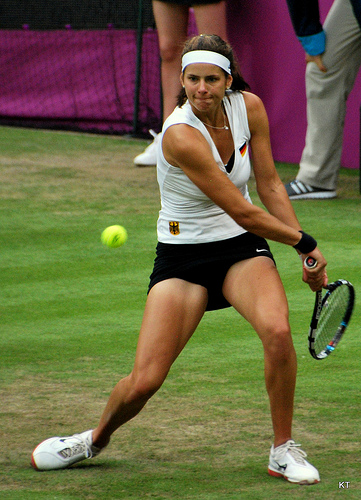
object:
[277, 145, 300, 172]
floor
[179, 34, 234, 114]
player's head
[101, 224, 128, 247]
ball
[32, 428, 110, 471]
shoes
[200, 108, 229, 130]
necklace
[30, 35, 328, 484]
player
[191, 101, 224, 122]
neck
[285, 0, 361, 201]
leg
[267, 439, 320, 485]
shoe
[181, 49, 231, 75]
head band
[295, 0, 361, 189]
pants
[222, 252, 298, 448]
womanleg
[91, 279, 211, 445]
womanleg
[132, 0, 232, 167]
persons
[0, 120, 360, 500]
court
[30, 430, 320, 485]
sneakers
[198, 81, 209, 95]
nose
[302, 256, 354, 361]
racket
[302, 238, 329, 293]
hands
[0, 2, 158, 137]
net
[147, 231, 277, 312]
shorts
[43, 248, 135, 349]
air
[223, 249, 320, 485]
leg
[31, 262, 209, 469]
leg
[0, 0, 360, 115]
background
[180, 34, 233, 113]
head